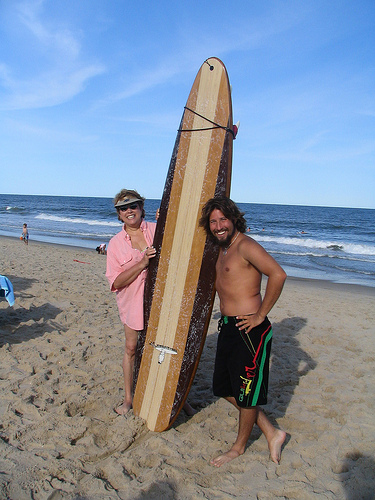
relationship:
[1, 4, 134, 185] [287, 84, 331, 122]
clouds in sky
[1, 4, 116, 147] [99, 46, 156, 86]
clouds in sky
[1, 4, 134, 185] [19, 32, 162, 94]
clouds in sky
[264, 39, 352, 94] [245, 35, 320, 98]
clouds in sky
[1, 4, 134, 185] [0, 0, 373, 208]
clouds in blue sky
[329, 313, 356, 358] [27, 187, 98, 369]
sand on beach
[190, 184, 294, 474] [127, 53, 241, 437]
man with a surfboard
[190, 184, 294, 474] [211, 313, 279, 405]
man wearing swim trunks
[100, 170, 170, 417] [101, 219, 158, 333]
woman wearing pink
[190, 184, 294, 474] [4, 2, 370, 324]
man posing for a picture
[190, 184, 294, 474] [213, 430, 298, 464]
man bare foot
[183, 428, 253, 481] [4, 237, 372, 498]
foot prints in sand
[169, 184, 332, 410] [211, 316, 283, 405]
man wearing shorts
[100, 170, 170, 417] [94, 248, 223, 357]
woman wearing pink shirt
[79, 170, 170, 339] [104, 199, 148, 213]
woman wearing sunglasses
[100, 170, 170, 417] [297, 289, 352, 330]
woman standing in sand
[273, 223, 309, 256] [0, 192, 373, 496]
waves crashing on beach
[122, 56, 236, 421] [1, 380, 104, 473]
surfboard in sand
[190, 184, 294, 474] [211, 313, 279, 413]
man wearing swim trunks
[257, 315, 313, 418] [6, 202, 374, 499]
shadow on ground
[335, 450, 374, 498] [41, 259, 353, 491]
shadow on ground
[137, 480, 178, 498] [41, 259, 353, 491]
shadow on ground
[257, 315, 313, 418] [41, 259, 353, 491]
shadow on ground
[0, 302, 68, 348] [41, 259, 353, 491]
shadow on ground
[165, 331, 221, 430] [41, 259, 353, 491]
shadow on ground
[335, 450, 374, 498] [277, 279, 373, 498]
shadow on ground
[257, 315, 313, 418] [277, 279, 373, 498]
shadow on ground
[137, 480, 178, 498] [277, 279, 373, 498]
shadow on ground